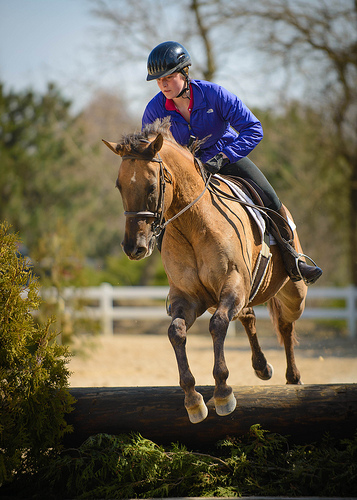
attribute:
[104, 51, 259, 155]
woman — riding, sitting, wearing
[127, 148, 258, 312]
horse — brown, jumping, leaping, jupming, here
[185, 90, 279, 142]
jacket — here, blue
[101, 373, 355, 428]
log — wooden, laying, large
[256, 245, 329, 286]
stirrup — metal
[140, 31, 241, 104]
helmet — strapped, black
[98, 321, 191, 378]
dirt — here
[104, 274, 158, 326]
fence — behind, wooden, white, background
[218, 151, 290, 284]
pants — black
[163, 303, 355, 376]
legs — brown, here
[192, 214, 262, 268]
fur — brown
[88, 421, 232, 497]
foilage — green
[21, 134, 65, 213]
leaves — green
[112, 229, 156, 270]
nose — brown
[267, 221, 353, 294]
boot — black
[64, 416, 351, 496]
greenery — beneath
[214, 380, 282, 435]
hoof — gray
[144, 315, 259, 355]
knees — brown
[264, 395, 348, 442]
tree — here